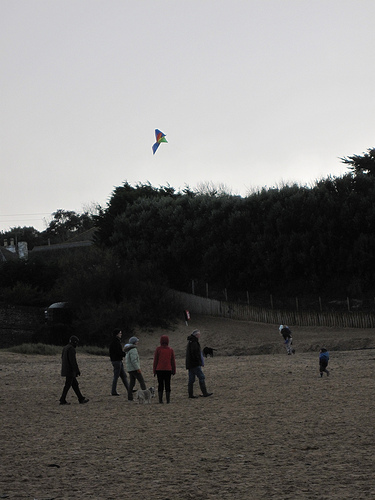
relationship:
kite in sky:
[146, 129, 164, 152] [194, 60, 217, 78]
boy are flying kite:
[317, 347, 329, 378] [146, 129, 164, 152]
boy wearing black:
[317, 347, 329, 378] [186, 349, 206, 363]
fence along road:
[213, 290, 267, 317] [188, 299, 222, 315]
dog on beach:
[285, 334, 296, 353] [0, 350, 375, 500]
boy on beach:
[317, 347, 329, 376] [0, 350, 375, 500]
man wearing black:
[51, 337, 87, 405] [186, 349, 206, 363]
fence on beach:
[213, 290, 267, 317] [197, 418, 252, 454]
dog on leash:
[285, 334, 296, 353] [200, 352, 220, 362]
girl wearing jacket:
[154, 340, 183, 406] [312, 349, 330, 361]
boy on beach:
[317, 347, 329, 376] [197, 418, 252, 454]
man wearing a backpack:
[51, 337, 87, 405] [105, 345, 120, 361]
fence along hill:
[213, 290, 267, 317] [59, 217, 97, 246]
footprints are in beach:
[191, 427, 209, 438] [197, 418, 252, 454]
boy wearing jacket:
[317, 347, 329, 378] [312, 349, 330, 361]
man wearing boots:
[51, 337, 87, 405] [122, 393, 139, 403]